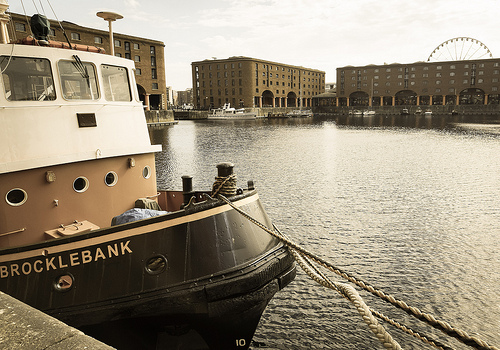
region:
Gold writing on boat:
[0, 234, 140, 282]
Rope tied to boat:
[207, 172, 497, 348]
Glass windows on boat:
[0, 50, 145, 110]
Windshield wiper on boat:
[67, 52, 104, 104]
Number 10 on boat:
[228, 334, 252, 349]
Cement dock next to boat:
[0, 287, 128, 348]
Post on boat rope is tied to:
[209, 156, 239, 206]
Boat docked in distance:
[196, 97, 271, 126]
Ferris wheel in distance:
[422, 28, 498, 75]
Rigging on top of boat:
[14, 0, 82, 57]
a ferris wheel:
[425, 33, 490, 61]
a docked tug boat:
[0, 13, 319, 348]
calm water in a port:
[277, 144, 456, 251]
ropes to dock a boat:
[214, 163, 485, 348]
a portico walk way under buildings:
[336, 83, 499, 113]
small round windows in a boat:
[67, 162, 123, 200]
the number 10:
[225, 328, 249, 349]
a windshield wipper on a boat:
[55, 48, 105, 104]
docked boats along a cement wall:
[280, 91, 465, 132]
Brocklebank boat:
[1, 233, 146, 308]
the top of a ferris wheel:
[422, 24, 494, 73]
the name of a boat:
[7, 229, 155, 296]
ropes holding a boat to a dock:
[262, 216, 406, 338]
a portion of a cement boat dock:
[7, 287, 63, 345]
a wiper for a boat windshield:
[65, 52, 98, 90]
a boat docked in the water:
[206, 98, 257, 125]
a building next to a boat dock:
[332, 56, 494, 118]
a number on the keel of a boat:
[230, 336, 249, 347]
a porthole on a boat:
[65, 174, 93, 201]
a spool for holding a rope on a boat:
[209, 159, 242, 203]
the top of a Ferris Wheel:
[424, 35, 495, 61]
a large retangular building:
[335, 58, 498, 108]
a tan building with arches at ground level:
[188, 55, 325, 110]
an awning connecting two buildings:
[312, 88, 338, 112]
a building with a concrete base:
[1, 9, 176, 126]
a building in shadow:
[171, 87, 194, 110]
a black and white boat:
[0, 36, 302, 348]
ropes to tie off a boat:
[212, 164, 498, 348]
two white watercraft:
[347, 108, 375, 115]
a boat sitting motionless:
[400, 105, 409, 114]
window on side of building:
[378, 65, 394, 75]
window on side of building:
[433, 63, 444, 75]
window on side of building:
[431, 71, 447, 81]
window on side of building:
[405, 72, 419, 77]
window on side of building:
[373, 64, 380, 74]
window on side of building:
[367, 71, 382, 80]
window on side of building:
[349, 75, 359, 82]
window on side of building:
[451, 71, 460, 80]